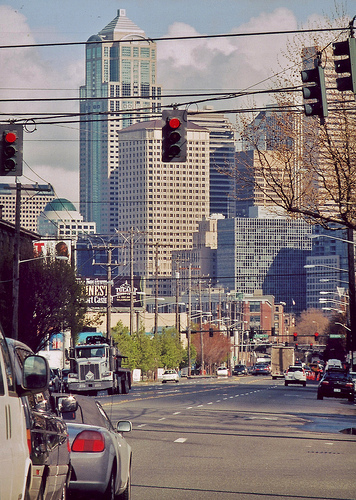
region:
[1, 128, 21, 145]
The red traffic light on the left.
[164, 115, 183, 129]
The red traffic light on the right.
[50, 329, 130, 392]
The truck on the left side of the street.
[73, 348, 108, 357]
The front window of the truck.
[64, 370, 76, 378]
The left headlight of the truck.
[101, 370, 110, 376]
The right headlight of the truck.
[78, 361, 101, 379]
The grill of the truck.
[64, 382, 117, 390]
The fender of the truck.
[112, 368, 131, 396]
The wheels on the side of the truck.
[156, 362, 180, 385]
The white car behind the truck.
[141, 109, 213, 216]
This is a stop light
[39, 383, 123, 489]
These are cars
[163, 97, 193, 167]
This is a red light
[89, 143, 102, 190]
This is a glass building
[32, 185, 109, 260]
This is a green dome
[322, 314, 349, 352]
This is a street sign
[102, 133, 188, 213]
These are windows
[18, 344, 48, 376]
This is a car mirror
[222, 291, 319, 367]
This is a brick building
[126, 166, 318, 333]
This is a city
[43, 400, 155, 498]
This is a car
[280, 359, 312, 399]
This is a car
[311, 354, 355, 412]
This is a car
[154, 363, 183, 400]
This is a car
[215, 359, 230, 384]
This is a car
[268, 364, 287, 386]
This is a car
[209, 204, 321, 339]
This is a tall building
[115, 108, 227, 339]
This is a tall building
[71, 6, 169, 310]
This is a tall building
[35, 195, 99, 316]
This is a tall building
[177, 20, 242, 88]
wire above the light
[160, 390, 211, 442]
white lines on the ground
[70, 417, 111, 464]
back light on the car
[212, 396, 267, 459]
shadows on the ground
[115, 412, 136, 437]
mirror on side of car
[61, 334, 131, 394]
truck on the street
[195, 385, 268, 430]
many white lines on the street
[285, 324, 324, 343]
two red lights above the street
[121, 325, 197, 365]
trees next to the road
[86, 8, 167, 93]
building in the distance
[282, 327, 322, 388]
white suv stopped in front of traffic light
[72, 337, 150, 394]
large truck on road in daytime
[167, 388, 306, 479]
view of street with shadows cast on it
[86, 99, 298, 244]
skyline of big city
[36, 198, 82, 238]
circular dome on top of building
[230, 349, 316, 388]
view of heavy traffic in background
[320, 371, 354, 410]
back side of black car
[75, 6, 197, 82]
top of large building with clouds in background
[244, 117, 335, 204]
tree with buds starting to form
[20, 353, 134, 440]
three side view mirrors on vehicles